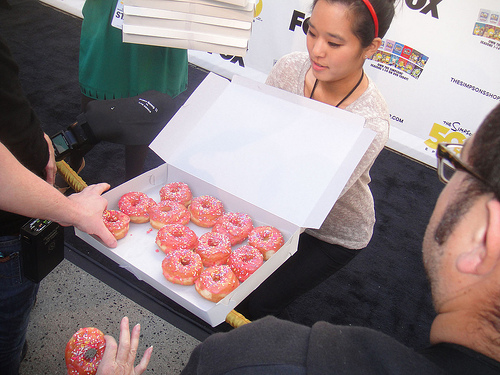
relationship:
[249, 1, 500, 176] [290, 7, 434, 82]
banner of advert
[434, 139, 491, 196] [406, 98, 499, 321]
glasses on head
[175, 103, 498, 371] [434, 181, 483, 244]
man has sideburn